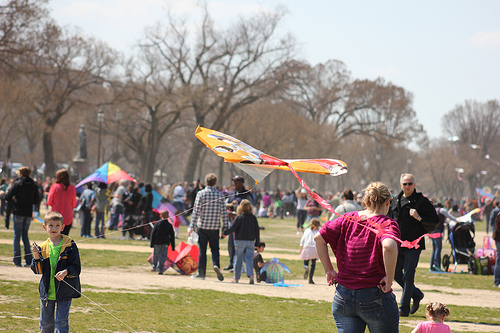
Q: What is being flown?
A: A kite.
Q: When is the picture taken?
A: Daytime.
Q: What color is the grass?
A: Green.